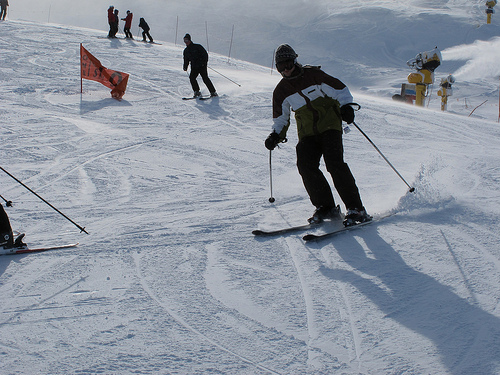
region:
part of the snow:
[393, 318, 412, 338]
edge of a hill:
[138, 181, 193, 288]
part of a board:
[313, 230, 320, 240]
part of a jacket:
[334, 170, 337, 178]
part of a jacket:
[311, 107, 321, 117]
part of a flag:
[120, 83, 125, 88]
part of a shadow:
[411, 266, 426, 286]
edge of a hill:
[426, 151, 437, 176]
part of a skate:
[348, 211, 360, 246]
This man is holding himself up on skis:
[279, 185, 367, 297]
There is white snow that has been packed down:
[166, 208, 209, 288]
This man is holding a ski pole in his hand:
[260, 140, 288, 207]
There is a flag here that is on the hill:
[74, 25, 139, 122]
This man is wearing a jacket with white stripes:
[281, 73, 329, 128]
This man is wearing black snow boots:
[350, 190, 396, 256]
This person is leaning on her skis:
[138, 17, 154, 52]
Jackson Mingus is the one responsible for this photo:
[121, 33, 408, 371]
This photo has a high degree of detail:
[99, 28, 393, 374]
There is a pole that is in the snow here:
[73, 75, 89, 113]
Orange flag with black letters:
[70, 42, 137, 98]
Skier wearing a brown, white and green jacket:
[246, 41, 373, 226]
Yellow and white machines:
[396, 52, 453, 113]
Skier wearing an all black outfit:
[176, 34, 229, 104]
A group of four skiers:
[102, 5, 158, 42]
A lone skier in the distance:
[0, 1, 15, 25]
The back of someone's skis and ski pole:
[0, 156, 99, 251]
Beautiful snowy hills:
[3, 3, 492, 373]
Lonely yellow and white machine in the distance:
[478, 0, 495, 26]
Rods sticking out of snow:
[175, 15, 282, 73]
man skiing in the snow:
[244, 32, 431, 265]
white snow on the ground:
[96, 265, 249, 365]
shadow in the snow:
[327, 239, 495, 374]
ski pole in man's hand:
[260, 144, 288, 211]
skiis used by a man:
[248, 217, 328, 264]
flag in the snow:
[69, 27, 139, 118]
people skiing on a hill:
[96, 0, 171, 59]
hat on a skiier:
[263, 39, 301, 62]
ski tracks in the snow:
[293, 267, 362, 356]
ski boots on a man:
[303, 205, 378, 225]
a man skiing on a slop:
[240, 36, 416, 260]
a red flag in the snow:
[73, 42, 132, 104]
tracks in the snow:
[94, 204, 273, 346]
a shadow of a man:
[290, 220, 498, 367]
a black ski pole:
[255, 141, 275, 217]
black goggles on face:
[271, 56, 298, 76]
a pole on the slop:
[228, 26, 235, 60]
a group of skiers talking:
[93, 1, 160, 43]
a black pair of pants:
[290, 136, 355, 205]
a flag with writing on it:
[72, 39, 131, 103]